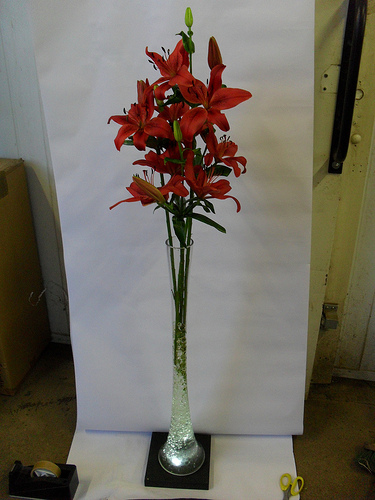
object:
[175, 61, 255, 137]
flower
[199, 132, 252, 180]
flower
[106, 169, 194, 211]
flower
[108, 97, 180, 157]
flower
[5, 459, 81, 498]
tape dispenser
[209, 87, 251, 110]
pedal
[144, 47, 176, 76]
pedal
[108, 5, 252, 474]
flower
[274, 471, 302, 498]
scissors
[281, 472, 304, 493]
handle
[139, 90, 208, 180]
flower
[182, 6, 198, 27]
flower bud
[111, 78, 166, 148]
flower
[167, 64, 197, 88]
pedal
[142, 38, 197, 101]
flower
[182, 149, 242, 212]
flower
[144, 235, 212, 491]
vase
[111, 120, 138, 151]
petal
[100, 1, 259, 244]
bouquet